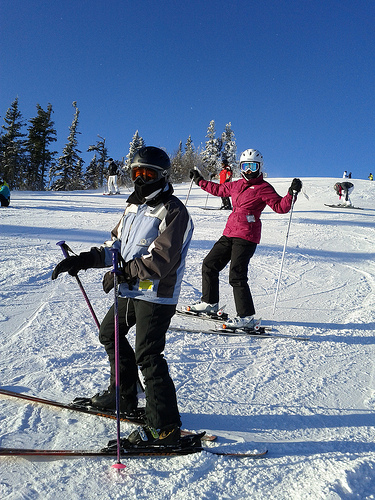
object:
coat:
[199, 172, 297, 244]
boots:
[220, 314, 261, 329]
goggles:
[241, 161, 259, 172]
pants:
[98, 297, 180, 428]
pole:
[109, 247, 127, 473]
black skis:
[170, 327, 280, 339]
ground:
[274, 89, 304, 118]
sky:
[1, 0, 373, 190]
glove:
[52, 255, 84, 280]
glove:
[103, 267, 128, 294]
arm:
[199, 176, 237, 197]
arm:
[262, 181, 295, 214]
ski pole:
[184, 176, 195, 206]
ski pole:
[272, 190, 297, 316]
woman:
[190, 144, 302, 328]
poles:
[184, 176, 194, 206]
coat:
[80, 182, 194, 305]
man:
[51, 146, 194, 446]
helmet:
[130, 146, 171, 200]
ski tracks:
[253, 209, 372, 344]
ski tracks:
[170, 340, 372, 419]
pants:
[201, 235, 257, 318]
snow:
[0, 176, 375, 500]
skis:
[176, 300, 229, 322]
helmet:
[240, 148, 264, 179]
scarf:
[339, 185, 342, 200]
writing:
[4, 447, 196, 459]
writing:
[0, 390, 171, 432]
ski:
[0, 388, 218, 442]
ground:
[0, 172, 372, 497]